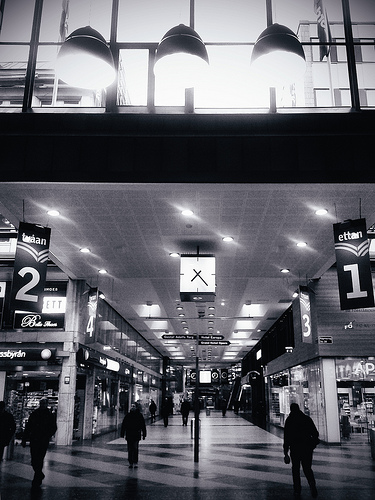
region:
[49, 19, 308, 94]
row of three lights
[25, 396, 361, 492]
walkway in the mall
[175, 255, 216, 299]
clock hanging from the ceiling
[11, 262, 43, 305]
white number 2 on black background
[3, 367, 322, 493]
people walking in the mall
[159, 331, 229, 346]
black signs with white lettering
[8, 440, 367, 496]
stripes on the floor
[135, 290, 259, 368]
square lights in the ceiling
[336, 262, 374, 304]
white number 1 on black background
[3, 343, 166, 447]
storefronts on the left side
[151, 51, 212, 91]
light fixture hanging down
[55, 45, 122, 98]
light fixture hanging down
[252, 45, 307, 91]
light fixture hanging down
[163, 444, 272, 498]
black and white tile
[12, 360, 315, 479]
people walking inside mall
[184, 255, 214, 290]
clock hanging down from ceiling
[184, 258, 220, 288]
white square clock from ceiling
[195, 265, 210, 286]
long black hand on clock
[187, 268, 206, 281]
short black hand on clock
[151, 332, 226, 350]
black signs with white writing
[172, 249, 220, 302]
LARGE HANGING MALL CLOCK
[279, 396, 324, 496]
PERSON SHOPPING IN MALL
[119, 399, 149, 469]
PERSON SHOPPING IN MALL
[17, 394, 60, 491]
PERSON SHOPPING IN MALL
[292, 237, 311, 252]
OVERHEAD LIGHT IN MALL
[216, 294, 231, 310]
OVERHEAD LIGHT IN MALL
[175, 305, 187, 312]
OVERHEAD LIGHT IN MALL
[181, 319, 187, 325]
OVERHEAD LIGHT IN MALL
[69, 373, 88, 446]
DOORWAY FOR MALL STORE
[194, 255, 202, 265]
NUMBER 12 ON MALL CLOCK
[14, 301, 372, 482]
people walking inside a mall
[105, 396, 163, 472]
this is a person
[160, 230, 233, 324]
this is a clock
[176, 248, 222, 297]
tick marks on clock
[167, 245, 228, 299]
clock face is white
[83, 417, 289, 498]
slanted stripes on the floor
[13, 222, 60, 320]
banners hanging from ceiling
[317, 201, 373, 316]
flag with 1 on it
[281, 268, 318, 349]
number 3 sign hanging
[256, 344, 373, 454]
side glass on store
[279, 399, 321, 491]
A person walking around.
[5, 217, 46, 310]
A number two sign.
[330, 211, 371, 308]
A number one sign.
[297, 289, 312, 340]
A number three sign.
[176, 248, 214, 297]
A lit up sign.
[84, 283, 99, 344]
A number four sign.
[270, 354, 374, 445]
A open store front.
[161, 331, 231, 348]
A group of signs.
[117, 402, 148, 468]
A person in a dark jacket.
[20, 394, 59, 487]
A person walking away.